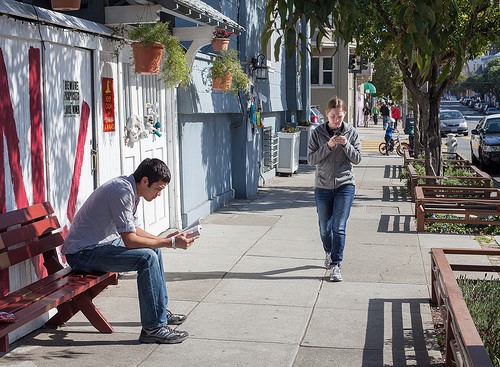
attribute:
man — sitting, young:
[62, 159, 173, 341]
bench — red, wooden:
[1, 240, 110, 356]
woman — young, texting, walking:
[319, 97, 345, 283]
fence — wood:
[410, 174, 487, 186]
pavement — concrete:
[198, 296, 301, 344]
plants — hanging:
[122, 23, 258, 101]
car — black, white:
[476, 116, 496, 158]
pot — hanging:
[130, 42, 160, 75]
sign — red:
[94, 73, 122, 133]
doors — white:
[125, 145, 164, 153]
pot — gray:
[276, 124, 295, 177]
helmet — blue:
[386, 117, 397, 123]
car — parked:
[437, 108, 470, 133]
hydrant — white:
[446, 135, 458, 160]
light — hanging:
[244, 57, 276, 82]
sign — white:
[56, 77, 80, 118]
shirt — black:
[380, 105, 391, 117]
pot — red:
[212, 66, 232, 99]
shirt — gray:
[320, 149, 353, 182]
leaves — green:
[214, 57, 240, 78]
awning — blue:
[4, 7, 114, 38]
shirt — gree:
[372, 107, 383, 116]